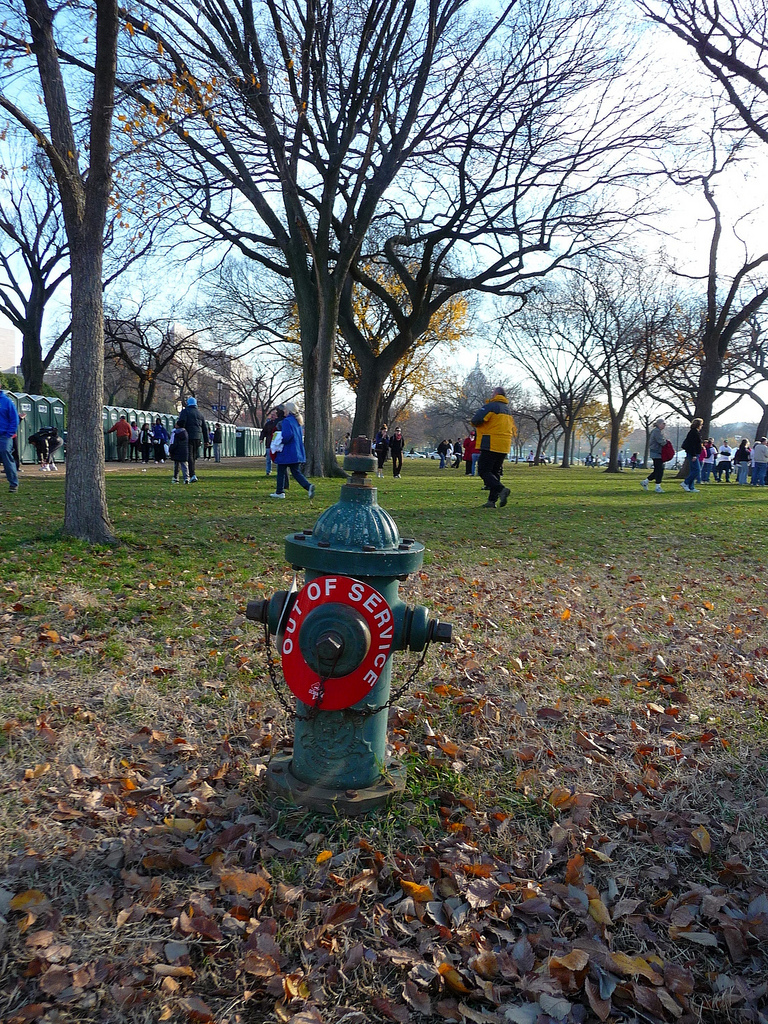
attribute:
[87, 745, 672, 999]
leaves — red, yellow, dry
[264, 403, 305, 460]
coat — blue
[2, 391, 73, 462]
toilets — temporary, mobile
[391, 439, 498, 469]
cars — parked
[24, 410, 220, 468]
people — gathered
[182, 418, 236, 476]
adult — walking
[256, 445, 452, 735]
hydrant — out of service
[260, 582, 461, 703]
sign — out of service, red, round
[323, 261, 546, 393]
tree — yellow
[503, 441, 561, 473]
people — sitting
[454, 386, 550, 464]
jacket — yellow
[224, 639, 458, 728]
chain — red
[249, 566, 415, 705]
sign — red, attached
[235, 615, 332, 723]
chain — attached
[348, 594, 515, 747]
chain — attached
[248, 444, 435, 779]
fire hydrant — green